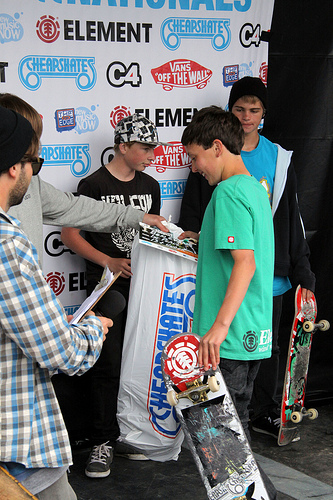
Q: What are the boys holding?
A: Skateboards.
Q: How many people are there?
A: Five.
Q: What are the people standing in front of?
A: Banner.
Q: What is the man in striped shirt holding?
A: A clipboard.